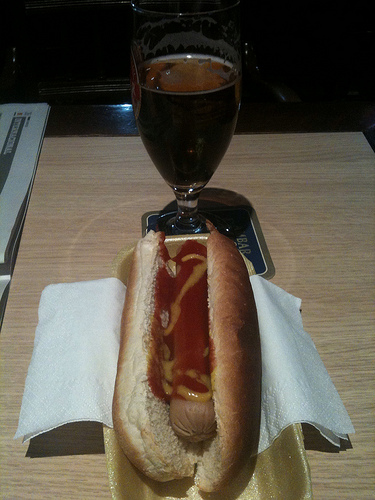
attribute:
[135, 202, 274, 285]
coaster — square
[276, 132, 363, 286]
table — wooden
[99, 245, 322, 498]
cup — yellow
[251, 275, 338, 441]
paper napkin — white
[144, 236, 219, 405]
ketchup — red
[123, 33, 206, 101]
glass — clear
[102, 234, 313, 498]
tray — yellow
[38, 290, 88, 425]
napkin — white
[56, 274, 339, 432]
napkin — white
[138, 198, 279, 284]
coaster — square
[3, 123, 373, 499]
table — wooden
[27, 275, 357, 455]
napkin — white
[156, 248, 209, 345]
cheese — melted